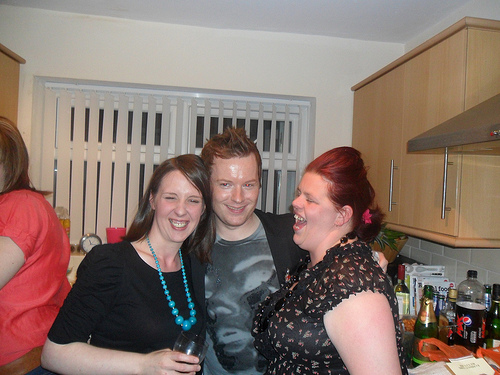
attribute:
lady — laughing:
[253, 144, 403, 374]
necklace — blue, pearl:
[142, 236, 197, 334]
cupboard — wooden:
[326, 21, 498, 261]